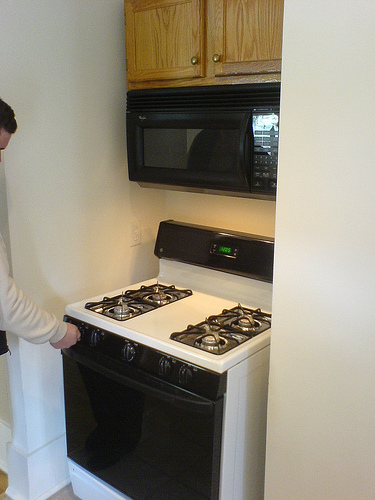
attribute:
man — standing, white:
[0, 99, 70, 499]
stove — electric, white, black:
[50, 223, 285, 499]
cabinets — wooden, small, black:
[111, 3, 290, 91]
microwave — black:
[116, 86, 282, 196]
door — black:
[61, 344, 223, 498]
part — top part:
[154, 218, 278, 284]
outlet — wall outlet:
[130, 222, 140, 245]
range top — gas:
[65, 279, 276, 375]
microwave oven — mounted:
[125, 84, 282, 200]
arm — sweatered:
[0, 241, 70, 345]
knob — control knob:
[77, 327, 84, 339]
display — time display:
[214, 242, 233, 256]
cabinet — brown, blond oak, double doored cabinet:
[126, 2, 284, 84]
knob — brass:
[190, 56, 197, 66]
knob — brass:
[212, 54, 224, 64]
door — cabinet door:
[122, 1, 207, 83]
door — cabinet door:
[213, 3, 281, 75]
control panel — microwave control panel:
[252, 113, 277, 197]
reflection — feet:
[88, 437, 135, 467]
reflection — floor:
[77, 405, 215, 495]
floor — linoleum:
[44, 484, 77, 498]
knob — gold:
[190, 57, 202, 66]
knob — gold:
[210, 55, 222, 63]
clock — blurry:
[217, 242, 231, 254]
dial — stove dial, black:
[122, 344, 136, 360]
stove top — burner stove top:
[67, 274, 272, 358]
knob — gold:
[190, 59, 195, 64]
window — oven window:
[65, 350, 227, 498]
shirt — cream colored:
[0, 255, 69, 344]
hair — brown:
[0, 96, 18, 132]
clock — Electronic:
[216, 246, 233, 254]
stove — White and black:
[64, 219, 271, 498]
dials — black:
[110, 340, 164, 374]